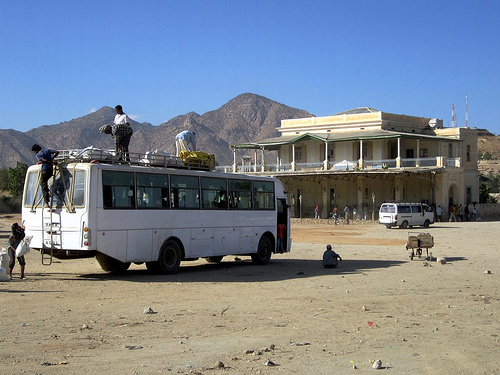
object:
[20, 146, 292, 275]
bus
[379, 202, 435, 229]
minivan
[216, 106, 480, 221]
building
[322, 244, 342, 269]
person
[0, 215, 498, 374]
ground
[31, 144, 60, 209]
man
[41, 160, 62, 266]
ladder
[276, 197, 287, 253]
door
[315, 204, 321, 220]
person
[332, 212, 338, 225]
person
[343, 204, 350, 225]
person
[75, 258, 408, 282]
shadow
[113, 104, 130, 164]
man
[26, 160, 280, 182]
roof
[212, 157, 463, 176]
balcony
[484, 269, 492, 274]
rock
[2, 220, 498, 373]
road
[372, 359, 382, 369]
rock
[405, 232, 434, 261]
buggy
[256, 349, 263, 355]
rocks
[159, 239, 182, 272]
tire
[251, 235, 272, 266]
tire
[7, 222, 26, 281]
person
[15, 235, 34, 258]
package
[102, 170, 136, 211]
window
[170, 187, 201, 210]
window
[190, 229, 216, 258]
unit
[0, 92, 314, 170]
line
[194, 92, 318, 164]
mountain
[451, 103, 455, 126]
tower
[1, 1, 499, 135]
sky